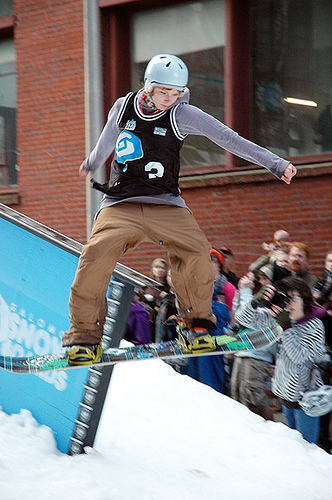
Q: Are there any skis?
A: No, there are no skis.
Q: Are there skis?
A: No, there are no skis.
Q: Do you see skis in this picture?
A: No, there are no skis.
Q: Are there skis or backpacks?
A: No, there are no skis or backpacks.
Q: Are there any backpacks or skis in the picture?
A: No, there are no skis or backpacks.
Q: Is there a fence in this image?
A: No, there are no fences.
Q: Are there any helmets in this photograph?
A: Yes, there is a helmet.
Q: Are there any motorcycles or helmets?
A: Yes, there is a helmet.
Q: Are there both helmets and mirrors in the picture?
A: No, there is a helmet but no mirrors.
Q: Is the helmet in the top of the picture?
A: Yes, the helmet is in the top of the image.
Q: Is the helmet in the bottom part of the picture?
A: No, the helmet is in the top of the image.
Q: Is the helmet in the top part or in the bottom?
A: The helmet is in the top of the image.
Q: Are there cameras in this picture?
A: Yes, there is a camera.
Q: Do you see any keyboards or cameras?
A: Yes, there is a camera.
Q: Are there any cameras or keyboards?
A: Yes, there is a camera.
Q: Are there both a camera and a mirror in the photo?
A: No, there is a camera but no mirrors.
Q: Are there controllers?
A: No, there are no controllers.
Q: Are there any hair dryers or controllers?
A: No, there are no controllers or hair dryers.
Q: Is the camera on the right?
A: Yes, the camera is on the right of the image.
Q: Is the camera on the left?
A: No, the camera is on the right of the image.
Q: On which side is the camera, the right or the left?
A: The camera is on the right of the image.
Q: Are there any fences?
A: No, there are no fences.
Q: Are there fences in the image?
A: No, there are no fences.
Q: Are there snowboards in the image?
A: Yes, there is a snowboard.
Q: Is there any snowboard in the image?
A: Yes, there is a snowboard.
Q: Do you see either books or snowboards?
A: Yes, there is a snowboard.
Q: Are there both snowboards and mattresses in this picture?
A: No, there is a snowboard but no mattresses.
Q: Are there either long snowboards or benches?
A: Yes, there is a long snowboard.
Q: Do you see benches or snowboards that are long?
A: Yes, the snowboard is long.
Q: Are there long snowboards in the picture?
A: Yes, there is a long snowboard.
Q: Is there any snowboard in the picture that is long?
A: Yes, there is a snowboard that is long.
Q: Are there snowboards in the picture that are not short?
A: Yes, there is a long snowboard.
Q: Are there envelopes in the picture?
A: No, there are no envelopes.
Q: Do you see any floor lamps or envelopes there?
A: No, there are no envelopes or floor lamps.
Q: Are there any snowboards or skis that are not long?
A: No, there is a snowboard but it is long.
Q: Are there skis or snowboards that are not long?
A: No, there is a snowboard but it is long.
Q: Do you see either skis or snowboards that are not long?
A: No, there is a snowboard but it is long.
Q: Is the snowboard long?
A: Yes, the snowboard is long.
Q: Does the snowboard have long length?
A: Yes, the snowboard is long.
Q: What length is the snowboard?
A: The snowboard is long.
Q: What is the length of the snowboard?
A: The snowboard is long.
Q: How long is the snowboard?
A: The snowboard is long.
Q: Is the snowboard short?
A: No, the snowboard is long.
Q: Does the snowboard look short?
A: No, the snowboard is long.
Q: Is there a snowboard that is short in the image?
A: No, there is a snowboard but it is long.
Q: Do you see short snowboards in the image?
A: No, there is a snowboard but it is long.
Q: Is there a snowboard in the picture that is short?
A: No, there is a snowboard but it is long.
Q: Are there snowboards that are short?
A: No, there is a snowboard but it is long.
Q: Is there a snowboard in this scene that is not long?
A: No, there is a snowboard but it is long.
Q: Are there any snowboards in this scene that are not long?
A: No, there is a snowboard but it is long.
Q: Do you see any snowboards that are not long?
A: No, there is a snowboard but it is long.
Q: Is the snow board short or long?
A: The snow board is long.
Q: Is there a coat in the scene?
A: Yes, there is a coat.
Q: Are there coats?
A: Yes, there is a coat.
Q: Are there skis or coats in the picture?
A: Yes, there is a coat.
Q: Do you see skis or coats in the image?
A: Yes, there is a coat.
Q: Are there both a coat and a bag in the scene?
A: No, there is a coat but no bags.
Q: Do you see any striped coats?
A: Yes, there is a striped coat.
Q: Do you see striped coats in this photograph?
A: Yes, there is a striped coat.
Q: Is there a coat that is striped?
A: Yes, there is a coat that is striped.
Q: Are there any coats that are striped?
A: Yes, there is a coat that is striped.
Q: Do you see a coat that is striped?
A: Yes, there is a coat that is striped.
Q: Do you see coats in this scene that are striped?
A: Yes, there is a coat that is striped.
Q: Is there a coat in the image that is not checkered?
A: Yes, there is a striped coat.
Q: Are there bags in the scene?
A: No, there are no bags.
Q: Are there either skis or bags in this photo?
A: No, there are no bags or skis.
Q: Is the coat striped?
A: Yes, the coat is striped.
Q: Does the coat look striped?
A: Yes, the coat is striped.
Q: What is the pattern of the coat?
A: The coat is striped.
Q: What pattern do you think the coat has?
A: The coat has striped pattern.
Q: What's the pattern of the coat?
A: The coat is striped.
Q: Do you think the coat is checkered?
A: No, the coat is striped.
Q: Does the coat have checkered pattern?
A: No, the coat is striped.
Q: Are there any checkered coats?
A: No, there is a coat but it is striped.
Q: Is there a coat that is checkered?
A: No, there is a coat but it is striped.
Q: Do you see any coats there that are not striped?
A: No, there is a coat but it is striped.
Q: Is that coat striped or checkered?
A: The coat is striped.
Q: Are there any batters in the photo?
A: No, there are no batters.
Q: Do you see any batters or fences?
A: No, there are no batters or fences.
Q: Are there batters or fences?
A: No, there are no batters or fences.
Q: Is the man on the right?
A: Yes, the man is on the right of the image.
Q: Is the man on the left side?
A: No, the man is on the right of the image.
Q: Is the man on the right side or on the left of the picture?
A: The man is on the right of the image.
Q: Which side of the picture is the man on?
A: The man is on the right of the image.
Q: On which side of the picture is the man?
A: The man is on the right of the image.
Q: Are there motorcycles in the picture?
A: No, there are no motorcycles.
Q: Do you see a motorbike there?
A: No, there are no motorcycles.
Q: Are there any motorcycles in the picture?
A: No, there are no motorcycles.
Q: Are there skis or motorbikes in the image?
A: No, there are no motorbikes or skis.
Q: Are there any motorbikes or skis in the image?
A: No, there are no motorbikes or skis.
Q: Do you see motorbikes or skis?
A: No, there are no motorbikes or skis.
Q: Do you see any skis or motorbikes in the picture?
A: No, there are no motorbikes or skis.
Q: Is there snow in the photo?
A: Yes, there is snow.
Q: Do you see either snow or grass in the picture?
A: Yes, there is snow.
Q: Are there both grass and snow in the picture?
A: No, there is snow but no grass.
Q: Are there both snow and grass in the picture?
A: No, there is snow but no grass.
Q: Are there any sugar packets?
A: No, there are no sugar packets.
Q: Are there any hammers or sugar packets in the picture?
A: No, there are no sugar packets or hammers.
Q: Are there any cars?
A: No, there are no cars.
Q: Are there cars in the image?
A: No, there are no cars.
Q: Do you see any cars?
A: No, there are no cars.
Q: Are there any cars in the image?
A: No, there are no cars.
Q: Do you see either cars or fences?
A: No, there are no cars or fences.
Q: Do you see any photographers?
A: Yes, there is a photographer.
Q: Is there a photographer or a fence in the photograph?
A: Yes, there is a photographer.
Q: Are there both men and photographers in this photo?
A: Yes, there are both a photographer and a man.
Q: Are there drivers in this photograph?
A: No, there are no drivers.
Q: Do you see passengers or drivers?
A: No, there are no drivers or passengers.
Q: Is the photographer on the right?
A: Yes, the photographer is on the right of the image.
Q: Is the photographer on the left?
A: No, the photographer is on the right of the image.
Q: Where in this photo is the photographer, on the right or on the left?
A: The photographer is on the right of the image.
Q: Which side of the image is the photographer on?
A: The photographer is on the right of the image.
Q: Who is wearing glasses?
A: The photographer is wearing glasses.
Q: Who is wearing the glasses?
A: The photographer is wearing glasses.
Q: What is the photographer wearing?
A: The photographer is wearing glasses.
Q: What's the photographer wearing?
A: The photographer is wearing glasses.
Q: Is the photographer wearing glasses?
A: Yes, the photographer is wearing glasses.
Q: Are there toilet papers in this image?
A: No, there are no toilet papers.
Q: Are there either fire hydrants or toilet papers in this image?
A: No, there are no toilet papers or fire hydrants.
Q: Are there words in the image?
A: Yes, there are words.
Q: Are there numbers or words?
A: Yes, there are words.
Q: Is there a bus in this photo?
A: No, there are no buses.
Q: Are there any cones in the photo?
A: No, there are no cones.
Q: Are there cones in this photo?
A: No, there are no cones.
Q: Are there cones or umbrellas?
A: No, there are no cones or umbrellas.